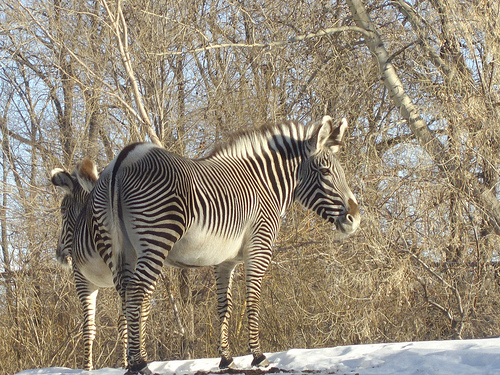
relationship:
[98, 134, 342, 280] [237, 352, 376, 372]
zebra in snow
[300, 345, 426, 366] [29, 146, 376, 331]
snow beneath zebras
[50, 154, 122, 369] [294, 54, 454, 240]
zebras by trees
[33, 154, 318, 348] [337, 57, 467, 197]
zebras near trees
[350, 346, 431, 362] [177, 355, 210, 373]
snow on ground